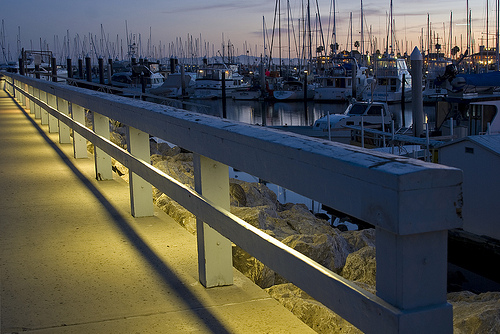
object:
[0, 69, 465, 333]
guard rail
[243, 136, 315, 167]
wood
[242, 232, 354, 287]
rocks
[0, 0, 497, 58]
sky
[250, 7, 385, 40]
clouds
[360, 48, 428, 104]
boats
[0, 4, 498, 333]
picture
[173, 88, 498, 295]
water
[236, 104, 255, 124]
light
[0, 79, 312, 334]
sidewalk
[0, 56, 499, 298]
bay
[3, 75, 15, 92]
lighting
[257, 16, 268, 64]
masts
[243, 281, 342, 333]
green growth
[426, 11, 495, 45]
sun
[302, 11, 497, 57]
sunset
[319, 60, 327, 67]
lights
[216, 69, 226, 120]
pole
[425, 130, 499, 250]
house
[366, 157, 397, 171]
chipped paint